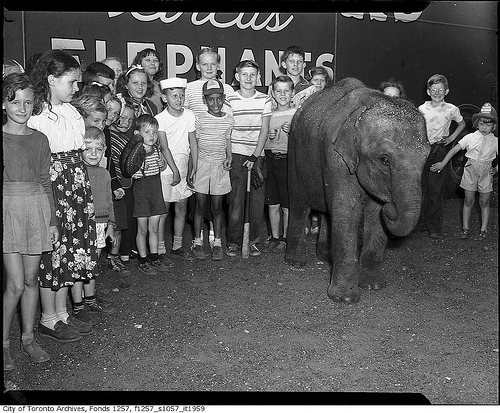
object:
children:
[0, 46, 495, 373]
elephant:
[284, 76, 432, 304]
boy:
[221, 59, 272, 258]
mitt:
[249, 157, 265, 190]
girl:
[432, 101, 500, 240]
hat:
[470, 101, 500, 123]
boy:
[152, 76, 199, 270]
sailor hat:
[160, 78, 188, 91]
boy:
[187, 78, 237, 260]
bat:
[242, 167, 253, 259]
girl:
[117, 64, 159, 120]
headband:
[125, 64, 146, 77]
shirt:
[25, 102, 87, 154]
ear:
[330, 103, 367, 175]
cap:
[202, 80, 224, 96]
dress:
[25, 103, 101, 291]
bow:
[125, 63, 144, 77]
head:
[121, 64, 148, 99]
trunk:
[382, 163, 424, 236]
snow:
[108, 291, 192, 357]